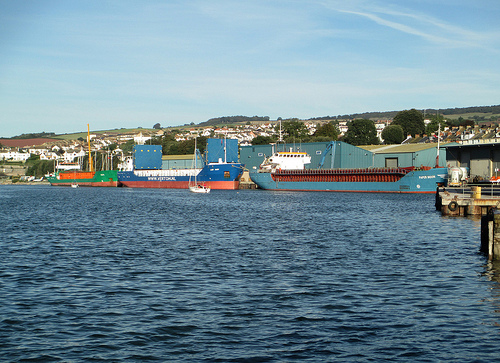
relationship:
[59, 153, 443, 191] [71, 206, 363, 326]
boats near water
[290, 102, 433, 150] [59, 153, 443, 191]
trees near boats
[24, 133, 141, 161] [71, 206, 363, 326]
houses near water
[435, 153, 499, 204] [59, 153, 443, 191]
pier near boats